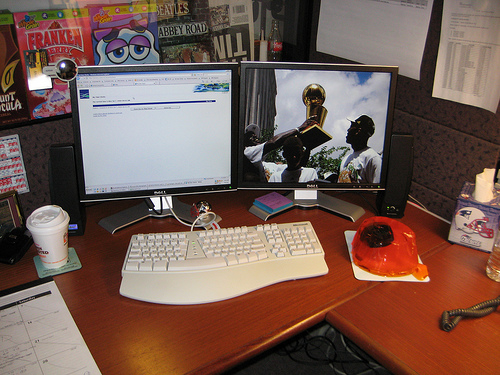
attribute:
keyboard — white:
[112, 213, 339, 314]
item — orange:
[343, 202, 442, 295]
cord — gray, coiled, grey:
[439, 291, 499, 342]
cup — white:
[20, 200, 79, 282]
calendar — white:
[1, 268, 100, 374]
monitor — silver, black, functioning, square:
[64, 44, 247, 210]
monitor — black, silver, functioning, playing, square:
[235, 45, 404, 212]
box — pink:
[6, 9, 102, 117]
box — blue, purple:
[80, 2, 167, 73]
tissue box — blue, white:
[444, 168, 498, 260]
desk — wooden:
[3, 186, 498, 374]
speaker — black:
[38, 135, 99, 238]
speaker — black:
[383, 126, 415, 223]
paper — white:
[425, 4, 500, 127]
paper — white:
[313, 0, 433, 84]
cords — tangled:
[270, 320, 375, 374]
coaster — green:
[25, 240, 85, 276]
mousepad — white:
[330, 217, 436, 291]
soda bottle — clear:
[482, 226, 499, 288]